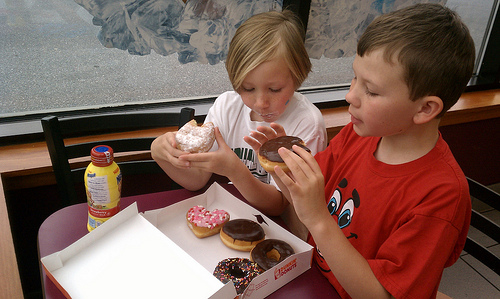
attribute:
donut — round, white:
[179, 122, 215, 150]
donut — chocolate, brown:
[258, 137, 306, 169]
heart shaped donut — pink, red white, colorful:
[188, 204, 225, 232]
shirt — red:
[317, 136, 466, 289]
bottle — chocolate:
[88, 146, 116, 226]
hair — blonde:
[225, 20, 307, 75]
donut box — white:
[35, 183, 309, 298]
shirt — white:
[211, 93, 313, 180]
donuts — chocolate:
[224, 222, 294, 267]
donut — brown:
[217, 257, 262, 290]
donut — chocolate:
[253, 241, 291, 271]